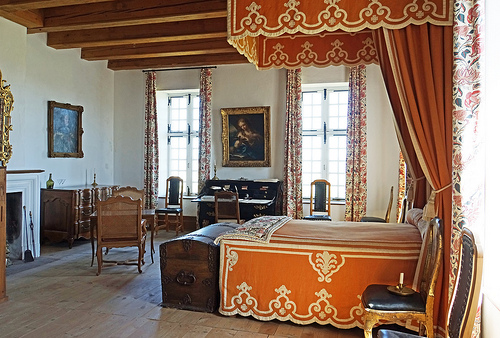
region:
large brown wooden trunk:
[156, 219, 231, 312]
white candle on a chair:
[386, 270, 418, 295]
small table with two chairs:
[86, 183, 156, 273]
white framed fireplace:
[3, 167, 42, 266]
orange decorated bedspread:
[216, 208, 441, 327]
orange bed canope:
[226, 0, 449, 240]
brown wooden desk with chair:
[198, 175, 281, 220]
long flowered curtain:
[341, 67, 371, 219]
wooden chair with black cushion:
[361, 216, 448, 336]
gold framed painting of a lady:
[218, 104, 270, 167]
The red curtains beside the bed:
[373, 28, 455, 322]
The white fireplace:
[3, 171, 48, 265]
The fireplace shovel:
[16, 202, 35, 264]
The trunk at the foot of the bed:
[155, 220, 241, 317]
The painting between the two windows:
[215, 103, 274, 171]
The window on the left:
[154, 88, 206, 198]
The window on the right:
[298, 78, 351, 216]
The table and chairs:
[85, 183, 160, 273]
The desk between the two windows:
[196, 175, 285, 220]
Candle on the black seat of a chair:
[390, 269, 413, 299]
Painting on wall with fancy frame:
[217, 104, 274, 168]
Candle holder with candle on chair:
[384, 265, 416, 302]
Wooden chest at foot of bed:
[160, 220, 240, 315]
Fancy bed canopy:
[211, 0, 452, 73]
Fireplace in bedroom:
[7, 167, 46, 262]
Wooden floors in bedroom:
[36, 278, 158, 332]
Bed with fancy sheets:
[220, 207, 438, 314]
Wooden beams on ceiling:
[48, 0, 228, 65]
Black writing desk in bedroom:
[194, 176, 281, 216]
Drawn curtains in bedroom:
[286, 74, 366, 173]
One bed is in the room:
[21, 18, 455, 335]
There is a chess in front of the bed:
[123, 127, 432, 312]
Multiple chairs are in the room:
[75, 170, 410, 327]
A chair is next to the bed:
[217, 209, 477, 326]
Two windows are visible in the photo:
[123, 80, 432, 292]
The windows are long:
[135, 68, 384, 270]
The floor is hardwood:
[52, 239, 210, 331]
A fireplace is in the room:
[3, 150, 88, 302]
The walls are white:
[37, 111, 350, 246]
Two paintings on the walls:
[55, 62, 357, 219]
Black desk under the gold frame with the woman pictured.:
[192, 172, 279, 224]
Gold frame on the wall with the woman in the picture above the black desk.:
[218, 103, 278, 170]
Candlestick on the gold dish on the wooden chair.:
[386, 273, 411, 296]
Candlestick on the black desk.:
[208, 158, 219, 178]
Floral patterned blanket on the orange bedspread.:
[215, 201, 292, 245]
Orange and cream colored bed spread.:
[226, 218, 423, 323]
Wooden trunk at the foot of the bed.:
[158, 212, 238, 312]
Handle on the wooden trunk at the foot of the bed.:
[172, 271, 198, 285]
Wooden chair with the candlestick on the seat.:
[366, 210, 444, 337]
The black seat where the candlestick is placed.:
[363, 282, 414, 312]